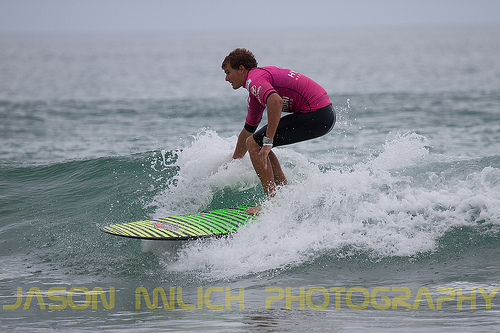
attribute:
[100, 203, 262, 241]
surfboard — multi colored, striped, yellow, green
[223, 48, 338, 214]
man — surfing, barefoot, outdoors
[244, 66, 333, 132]
shirt — pink, white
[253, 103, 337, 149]
swimming shorts — black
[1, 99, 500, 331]
wave — frothy, splashing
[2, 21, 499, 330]
water — green, rippling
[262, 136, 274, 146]
watch — grey, white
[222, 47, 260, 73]
hair — short, brown